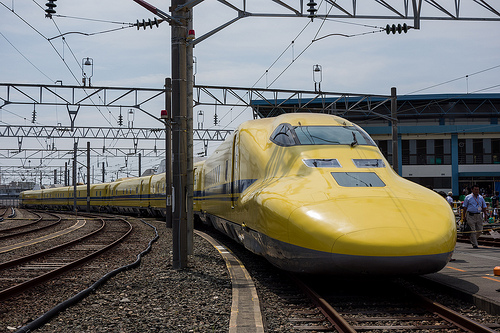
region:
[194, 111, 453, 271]
a yellow train engine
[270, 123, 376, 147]
windshield of a yellow train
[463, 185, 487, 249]
a man in a blue shirt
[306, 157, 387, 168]
front lights of a yellow train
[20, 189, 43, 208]
rear car of a yellow train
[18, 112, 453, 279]
a long yellow train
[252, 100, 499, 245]
a building behind a yellow train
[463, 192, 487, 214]
a man's blue shirt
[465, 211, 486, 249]
a man's tan pants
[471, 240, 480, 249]
a man's right shoe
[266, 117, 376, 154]
the windshield of a train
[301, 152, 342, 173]
a light on the train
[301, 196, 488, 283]
the nose of a train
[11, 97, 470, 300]
a yellow and black train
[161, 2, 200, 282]
a brown wooden pole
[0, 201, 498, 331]
sets of train tracks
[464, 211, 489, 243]
a pair of khaki pants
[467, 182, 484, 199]
the head of a man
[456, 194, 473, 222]
the arm of a man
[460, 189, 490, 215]
a blue shirt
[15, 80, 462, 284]
The train is yellow.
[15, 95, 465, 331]
The train on tracks.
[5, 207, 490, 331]
The tracks are brown.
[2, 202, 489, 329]
Gravel is between tracks.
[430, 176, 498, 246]
People waiting for train.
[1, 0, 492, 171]
The sky is blue.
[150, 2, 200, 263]
The pole is wooden.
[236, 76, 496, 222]
Train station is blue.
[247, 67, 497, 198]
Train station in distance.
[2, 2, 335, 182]
The wires are black.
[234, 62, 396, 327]
the train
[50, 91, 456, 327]
the train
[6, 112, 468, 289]
a bright yellow train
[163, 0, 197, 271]
a group of tall poles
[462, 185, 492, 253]
a man walking beside a train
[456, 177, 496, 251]
a man wearing a blue shirt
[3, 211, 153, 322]
two empty train tracks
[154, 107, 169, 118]
a small red light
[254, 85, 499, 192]
a building with blue trim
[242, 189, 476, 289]
the rounded front of a train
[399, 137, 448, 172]
a row of three windows